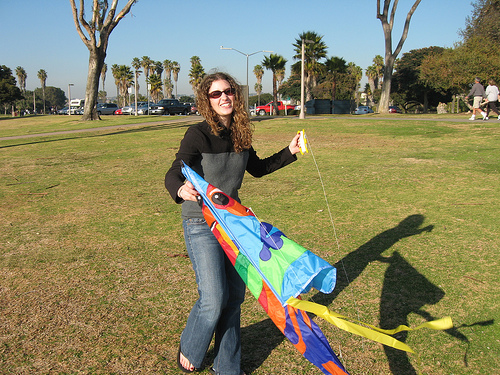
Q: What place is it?
A: It is a park.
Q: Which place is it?
A: It is a park.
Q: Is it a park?
A: Yes, it is a park.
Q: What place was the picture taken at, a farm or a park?
A: It was taken at a park.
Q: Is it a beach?
A: No, it is a park.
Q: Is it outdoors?
A: Yes, it is outdoors.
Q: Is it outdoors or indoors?
A: It is outdoors.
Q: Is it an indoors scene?
A: No, it is outdoors.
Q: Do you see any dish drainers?
A: No, there are no dish drainers.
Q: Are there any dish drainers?
A: No, there are no dish drainers.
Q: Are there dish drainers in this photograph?
A: No, there are no dish drainers.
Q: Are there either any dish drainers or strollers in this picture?
A: No, there are no dish drainers or strollers.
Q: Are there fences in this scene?
A: No, there are no fences.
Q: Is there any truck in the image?
A: Yes, there is a truck.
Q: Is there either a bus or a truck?
A: Yes, there is a truck.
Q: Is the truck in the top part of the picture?
A: Yes, the truck is in the top of the image.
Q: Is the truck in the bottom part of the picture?
A: No, the truck is in the top of the image.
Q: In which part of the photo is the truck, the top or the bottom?
A: The truck is in the top of the image.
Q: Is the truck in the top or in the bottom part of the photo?
A: The truck is in the top of the image.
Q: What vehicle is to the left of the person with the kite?
A: The vehicle is a truck.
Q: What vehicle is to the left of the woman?
A: The vehicle is a truck.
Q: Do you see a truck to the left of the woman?
A: Yes, there is a truck to the left of the woman.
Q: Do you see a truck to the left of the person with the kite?
A: Yes, there is a truck to the left of the woman.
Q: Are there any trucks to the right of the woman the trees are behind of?
A: No, the truck is to the left of the woman.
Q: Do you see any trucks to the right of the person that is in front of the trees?
A: No, the truck is to the left of the woman.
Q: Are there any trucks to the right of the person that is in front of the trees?
A: No, the truck is to the left of the woman.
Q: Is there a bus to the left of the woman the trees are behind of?
A: No, there is a truck to the left of the woman.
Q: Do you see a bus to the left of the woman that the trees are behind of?
A: No, there is a truck to the left of the woman.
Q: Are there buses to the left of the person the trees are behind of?
A: No, there is a truck to the left of the woman.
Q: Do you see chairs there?
A: No, there are no chairs.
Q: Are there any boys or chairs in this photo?
A: No, there are no chairs or boys.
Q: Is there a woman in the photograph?
A: Yes, there is a woman.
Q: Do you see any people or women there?
A: Yes, there is a woman.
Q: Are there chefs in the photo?
A: No, there are no chefs.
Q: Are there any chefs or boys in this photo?
A: No, there are no chefs or boys.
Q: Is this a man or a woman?
A: This is a woman.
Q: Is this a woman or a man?
A: This is a woman.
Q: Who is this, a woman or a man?
A: This is a woman.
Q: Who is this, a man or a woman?
A: This is a woman.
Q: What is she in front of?
A: The woman is in front of the trees.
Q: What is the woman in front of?
A: The woman is in front of the trees.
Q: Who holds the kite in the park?
A: The woman holds the kite.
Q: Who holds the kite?
A: The woman holds the kite.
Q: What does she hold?
A: The woman holds the kite.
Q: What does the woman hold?
A: The woman holds the kite.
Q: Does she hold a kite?
A: Yes, the woman holds a kite.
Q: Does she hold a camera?
A: No, the woman holds a kite.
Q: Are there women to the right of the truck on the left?
A: Yes, there is a woman to the right of the truck.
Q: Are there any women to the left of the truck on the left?
A: No, the woman is to the right of the truck.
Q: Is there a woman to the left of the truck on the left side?
A: No, the woman is to the right of the truck.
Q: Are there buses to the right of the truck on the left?
A: No, there is a woman to the right of the truck.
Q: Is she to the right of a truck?
A: Yes, the woman is to the right of a truck.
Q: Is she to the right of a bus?
A: No, the woman is to the right of a truck.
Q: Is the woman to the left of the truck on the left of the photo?
A: No, the woman is to the right of the truck.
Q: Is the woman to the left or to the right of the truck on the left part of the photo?
A: The woman is to the right of the truck.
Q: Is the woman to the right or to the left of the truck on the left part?
A: The woman is to the right of the truck.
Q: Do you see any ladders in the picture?
A: No, there are no ladders.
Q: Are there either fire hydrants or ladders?
A: No, there are no ladders or fire hydrants.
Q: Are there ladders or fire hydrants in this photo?
A: No, there are no ladders or fire hydrants.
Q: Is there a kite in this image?
A: Yes, there is a kite.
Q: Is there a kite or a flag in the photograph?
A: Yes, there is a kite.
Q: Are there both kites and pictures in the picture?
A: No, there is a kite but no pictures.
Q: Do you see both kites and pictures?
A: No, there is a kite but no pictures.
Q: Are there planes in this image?
A: No, there are no planes.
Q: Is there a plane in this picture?
A: No, there are no airplanes.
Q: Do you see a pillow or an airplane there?
A: No, there are no airplanes or pillows.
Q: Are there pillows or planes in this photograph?
A: No, there are no planes or pillows.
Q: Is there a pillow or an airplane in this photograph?
A: No, there are no airplanes or pillows.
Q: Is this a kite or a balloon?
A: This is a kite.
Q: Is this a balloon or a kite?
A: This is a kite.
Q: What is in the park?
A: The kite is in the park.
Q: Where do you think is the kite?
A: The kite is in the park.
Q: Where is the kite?
A: The kite is in the park.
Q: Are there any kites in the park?
A: Yes, there is a kite in the park.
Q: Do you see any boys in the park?
A: No, there is a kite in the park.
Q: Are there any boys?
A: No, there are no boys.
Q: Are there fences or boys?
A: No, there are no boys or fences.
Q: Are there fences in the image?
A: No, there are no fences.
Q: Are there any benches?
A: No, there are no benches.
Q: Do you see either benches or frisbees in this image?
A: No, there are no benches or frisbees.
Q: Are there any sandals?
A: Yes, there are sandals.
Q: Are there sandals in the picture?
A: Yes, there are sandals.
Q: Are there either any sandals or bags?
A: Yes, there are sandals.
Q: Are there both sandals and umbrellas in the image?
A: No, there are sandals but no umbrellas.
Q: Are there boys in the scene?
A: No, there are no boys.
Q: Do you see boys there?
A: No, there are no boys.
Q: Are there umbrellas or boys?
A: No, there are no boys or umbrellas.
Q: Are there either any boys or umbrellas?
A: No, there are no boys or umbrellas.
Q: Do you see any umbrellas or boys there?
A: No, there are no boys or umbrellas.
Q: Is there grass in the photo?
A: Yes, there is grass.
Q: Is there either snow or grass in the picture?
A: Yes, there is grass.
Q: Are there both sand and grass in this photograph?
A: No, there is grass but no sand.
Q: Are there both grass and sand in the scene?
A: No, there is grass but no sand.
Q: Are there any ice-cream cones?
A: No, there are no ice-cream cones.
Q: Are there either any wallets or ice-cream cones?
A: No, there are no ice-cream cones or wallets.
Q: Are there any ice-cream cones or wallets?
A: No, there are no ice-cream cones or wallets.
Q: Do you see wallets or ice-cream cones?
A: No, there are no ice-cream cones or wallets.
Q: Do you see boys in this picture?
A: No, there are no boys.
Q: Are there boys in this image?
A: No, there are no boys.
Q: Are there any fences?
A: No, there are no fences.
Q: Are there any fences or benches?
A: No, there are no fences or benches.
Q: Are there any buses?
A: No, there are no buses.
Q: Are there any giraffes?
A: No, there are no giraffes.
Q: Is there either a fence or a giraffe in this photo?
A: No, there are no giraffes or fences.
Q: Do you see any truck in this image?
A: Yes, there is a truck.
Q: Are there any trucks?
A: Yes, there is a truck.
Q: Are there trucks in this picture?
A: Yes, there is a truck.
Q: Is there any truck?
A: Yes, there is a truck.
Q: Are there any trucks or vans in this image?
A: Yes, there is a truck.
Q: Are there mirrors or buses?
A: No, there are no buses or mirrors.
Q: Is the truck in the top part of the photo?
A: Yes, the truck is in the top of the image.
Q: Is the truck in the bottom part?
A: No, the truck is in the top of the image.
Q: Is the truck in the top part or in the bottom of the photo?
A: The truck is in the top of the image.